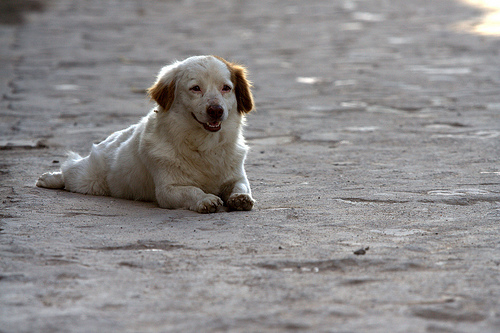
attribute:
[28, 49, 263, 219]
pup — furry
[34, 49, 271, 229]
dog — laying down, brown, white, happy, smiling, content, lying, subject, dirty, light brown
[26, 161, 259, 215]
legs — stretched out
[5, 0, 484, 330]
ground — sandy, sand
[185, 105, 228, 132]
mouth — open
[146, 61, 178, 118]
ear — brown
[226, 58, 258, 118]
ear — brown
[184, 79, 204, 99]
eye — black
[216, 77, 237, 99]
eye — black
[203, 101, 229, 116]
nose — black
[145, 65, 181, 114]
ear — brown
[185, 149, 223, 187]
chest — furry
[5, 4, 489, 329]
dirt ground — uneven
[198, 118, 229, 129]
teeth — showing